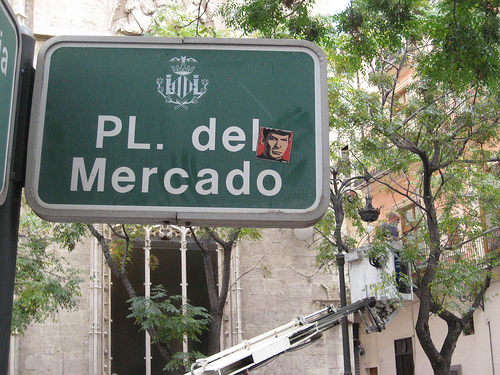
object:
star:
[258, 129, 294, 163]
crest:
[154, 53, 211, 110]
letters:
[70, 116, 286, 198]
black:
[1, 19, 34, 375]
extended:
[182, 237, 419, 374]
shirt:
[373, 224, 404, 246]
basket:
[345, 239, 416, 312]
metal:
[395, 336, 413, 374]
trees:
[43, 0, 328, 374]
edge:
[1, 1, 24, 216]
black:
[328, 172, 381, 374]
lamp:
[359, 194, 384, 233]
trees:
[350, 1, 497, 375]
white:
[164, 297, 374, 374]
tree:
[0, 195, 78, 371]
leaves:
[319, 1, 498, 316]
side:
[323, 34, 499, 374]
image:
[255, 126, 293, 163]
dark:
[109, 237, 221, 374]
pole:
[330, 159, 380, 374]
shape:
[141, 252, 162, 273]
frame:
[89, 220, 245, 374]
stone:
[89, 222, 245, 374]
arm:
[176, 295, 378, 374]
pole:
[1, 23, 38, 372]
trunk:
[422, 354, 464, 373]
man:
[371, 207, 407, 247]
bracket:
[10, 60, 36, 193]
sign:
[36, 26, 332, 233]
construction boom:
[185, 286, 400, 373]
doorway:
[98, 223, 223, 372]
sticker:
[264, 125, 294, 163]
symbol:
[144, 53, 212, 113]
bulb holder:
[349, 170, 389, 230]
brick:
[369, 192, 403, 206]